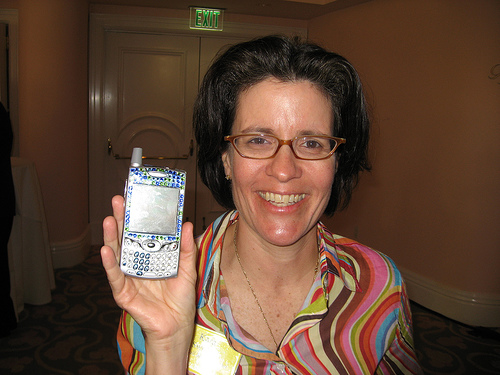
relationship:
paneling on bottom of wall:
[398, 268, 498, 328] [308, 0, 498, 328]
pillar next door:
[14, 23, 99, 274] [86, 17, 216, 252]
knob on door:
[7, 150, 36, 173] [11, 13, 52, 348]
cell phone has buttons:
[119, 147, 187, 279] [119, 238, 183, 278]